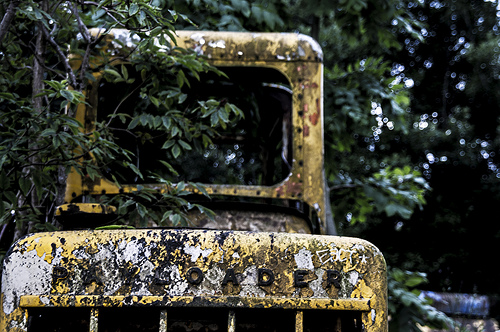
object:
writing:
[81, 265, 104, 287]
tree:
[0, 15, 243, 244]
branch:
[30, 28, 46, 117]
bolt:
[296, 127, 303, 134]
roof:
[71, 28, 324, 67]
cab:
[63, 28, 327, 197]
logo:
[47, 266, 345, 289]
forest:
[4, 0, 497, 328]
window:
[84, 64, 294, 187]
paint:
[18, 227, 51, 263]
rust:
[308, 96, 320, 126]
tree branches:
[226, 0, 500, 228]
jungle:
[0, 3, 495, 328]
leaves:
[384, 201, 413, 220]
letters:
[49, 265, 74, 288]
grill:
[16, 303, 373, 332]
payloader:
[0, 26, 388, 332]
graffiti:
[316, 245, 367, 265]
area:
[1, 247, 63, 312]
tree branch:
[30, 14, 47, 125]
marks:
[155, 228, 185, 250]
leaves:
[171, 125, 180, 138]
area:
[275, 170, 309, 197]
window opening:
[93, 65, 296, 185]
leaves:
[172, 144, 181, 159]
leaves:
[162, 137, 176, 149]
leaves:
[201, 106, 216, 118]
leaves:
[138, 112, 149, 127]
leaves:
[161, 116, 171, 131]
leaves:
[126, 160, 143, 179]